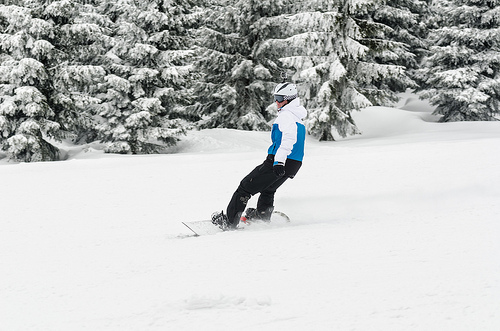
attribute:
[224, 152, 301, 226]
pants — black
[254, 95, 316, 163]
blue jacket — white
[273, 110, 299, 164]
sleeve — white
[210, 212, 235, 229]
shoe — black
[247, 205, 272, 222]
shoe — black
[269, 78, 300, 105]
hat — white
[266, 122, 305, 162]
coat — blue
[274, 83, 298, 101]
helmet — white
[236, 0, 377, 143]
tree — snowy, pine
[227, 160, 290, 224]
pants — black, snow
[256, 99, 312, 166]
jacket — hooded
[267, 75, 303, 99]
helmet — white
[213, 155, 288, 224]
pants — black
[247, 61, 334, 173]
shirt. — blue, white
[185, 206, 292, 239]
snowboard — tilted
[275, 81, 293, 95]
stripe — black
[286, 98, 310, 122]
hood — white